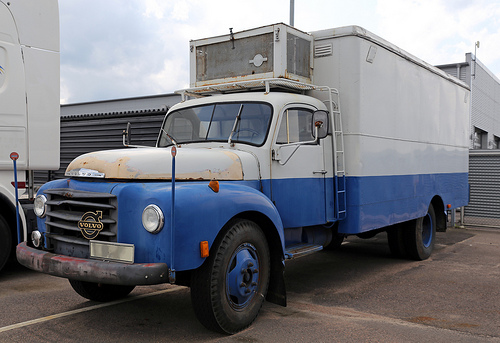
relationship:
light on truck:
[138, 201, 164, 235] [20, 18, 482, 337]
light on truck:
[31, 193, 48, 221] [20, 18, 482, 337]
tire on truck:
[189, 212, 282, 340] [20, 18, 482, 337]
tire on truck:
[387, 197, 441, 265] [20, 18, 482, 337]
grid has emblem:
[35, 186, 124, 263] [76, 209, 107, 244]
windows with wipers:
[154, 98, 276, 155] [226, 99, 249, 149]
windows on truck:
[154, 98, 276, 155] [20, 18, 482, 337]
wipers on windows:
[226, 99, 249, 149] [154, 98, 276, 155]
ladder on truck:
[315, 80, 351, 220] [20, 18, 482, 337]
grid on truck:
[35, 186, 124, 263] [20, 18, 482, 337]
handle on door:
[314, 166, 328, 180] [264, 95, 332, 233]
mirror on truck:
[308, 102, 331, 138] [20, 18, 482, 337]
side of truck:
[315, 31, 484, 240] [20, 18, 482, 337]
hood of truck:
[66, 140, 247, 186] [20, 18, 482, 337]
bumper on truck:
[13, 236, 174, 296] [20, 18, 482, 337]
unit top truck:
[181, 18, 320, 99] [20, 18, 482, 337]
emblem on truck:
[76, 209, 107, 244] [20, 18, 482, 337]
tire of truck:
[189, 212, 282, 340] [20, 18, 482, 337]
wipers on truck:
[226, 99, 249, 149] [20, 18, 482, 337]